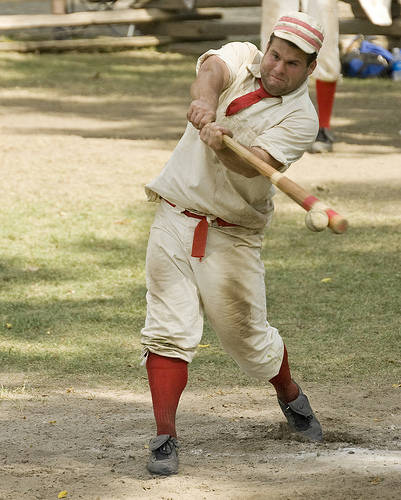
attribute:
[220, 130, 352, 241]
bat — wooden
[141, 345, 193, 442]
sock — red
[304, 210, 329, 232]
baseball — white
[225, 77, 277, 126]
tie — red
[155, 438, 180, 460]
laces — Black 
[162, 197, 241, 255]
belt — red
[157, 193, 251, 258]
belt — red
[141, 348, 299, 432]
socks — red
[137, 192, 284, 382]
pants — white, red, black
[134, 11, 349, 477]
batter — Swinging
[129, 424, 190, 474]
cleat — Black , Dirt 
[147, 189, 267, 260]
belt — red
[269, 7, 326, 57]
hat — white, red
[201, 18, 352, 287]
man — White 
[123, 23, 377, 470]
man — batter, white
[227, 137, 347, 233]
baseball bat — brown, white, red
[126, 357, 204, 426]
sock — red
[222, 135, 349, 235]
bat — Wooden , brown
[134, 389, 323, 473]
shoes — black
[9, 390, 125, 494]
dirt — brown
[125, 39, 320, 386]
uniform — red